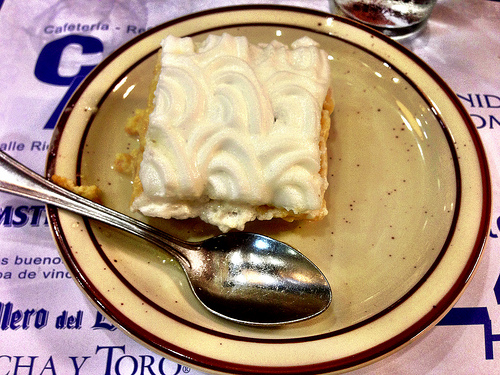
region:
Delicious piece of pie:
[118, 28, 368, 237]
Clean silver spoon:
[5, 167, 348, 329]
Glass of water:
[319, 0, 456, 47]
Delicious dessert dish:
[0, 17, 496, 369]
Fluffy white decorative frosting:
[128, 25, 348, 223]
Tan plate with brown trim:
[15, 15, 495, 373]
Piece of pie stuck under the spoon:
[37, 147, 112, 227]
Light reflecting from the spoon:
[210, 235, 305, 310]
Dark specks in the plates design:
[340, 140, 430, 263]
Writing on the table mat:
[1, 125, 194, 373]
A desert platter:
[19, 10, 456, 361]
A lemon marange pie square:
[156, 106, 347, 228]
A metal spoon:
[24, 186, 326, 319]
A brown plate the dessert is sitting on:
[373, 70, 437, 298]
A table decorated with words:
[7, 16, 62, 111]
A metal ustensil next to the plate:
[318, 0, 435, 31]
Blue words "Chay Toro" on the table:
[10, 345, 192, 371]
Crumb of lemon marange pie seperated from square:
[60, 172, 96, 190]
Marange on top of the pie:
[194, 63, 296, 178]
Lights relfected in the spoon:
[221, 251, 292, 283]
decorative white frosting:
[143, 36, 320, 213]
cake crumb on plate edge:
[48, 155, 108, 201]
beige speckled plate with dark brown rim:
[48, 6, 490, 373]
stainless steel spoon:
[1, 146, 331, 326]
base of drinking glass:
[332, 0, 436, 43]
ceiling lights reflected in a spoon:
[189, 234, 328, 304]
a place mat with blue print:
[1, 0, 136, 374]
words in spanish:
[0, 252, 92, 335]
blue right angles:
[442, 298, 499, 367]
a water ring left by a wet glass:
[19, 0, 148, 72]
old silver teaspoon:
[2, 151, 332, 326]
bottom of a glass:
[328, 0, 435, 39]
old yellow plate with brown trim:
[51, 13, 493, 370]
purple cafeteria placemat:
[2, 4, 495, 372]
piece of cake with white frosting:
[127, 48, 329, 236]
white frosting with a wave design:
[136, 35, 321, 218]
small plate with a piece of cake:
[47, 6, 490, 373]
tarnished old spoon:
[2, 150, 332, 325]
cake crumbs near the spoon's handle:
[48, 174, 98, 204]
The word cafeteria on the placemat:
[39, 20, 114, 35]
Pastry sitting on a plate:
[119, 24, 339, 221]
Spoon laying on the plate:
[57, 185, 364, 331]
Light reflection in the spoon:
[222, 241, 283, 291]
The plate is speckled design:
[355, 138, 437, 253]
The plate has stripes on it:
[410, 203, 494, 316]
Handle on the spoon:
[7, 156, 146, 258]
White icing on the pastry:
[144, 95, 379, 202]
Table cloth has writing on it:
[0, 279, 99, 366]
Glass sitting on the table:
[327, 1, 433, 40]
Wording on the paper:
[31, 16, 123, 116]